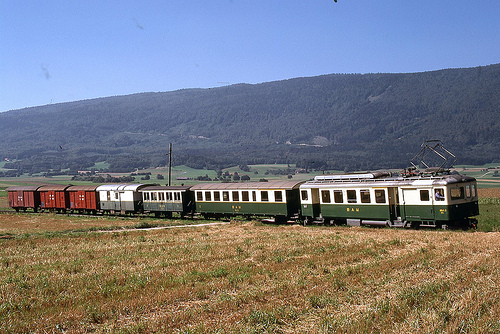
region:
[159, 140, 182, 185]
Tall brown telephone pole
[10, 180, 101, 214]
Three red train cars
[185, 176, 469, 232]
Two green and white train cars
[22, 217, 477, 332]
Brown grassy field in front of train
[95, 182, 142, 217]
One white and gray train car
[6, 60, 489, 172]
Hill covered with dark green trees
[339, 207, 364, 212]
Yellow train sign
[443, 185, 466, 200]
Open train window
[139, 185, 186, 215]
Green and white train car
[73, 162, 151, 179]
Brown patch of dirt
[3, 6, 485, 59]
this is the sky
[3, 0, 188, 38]
the sky is blue in color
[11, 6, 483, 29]
the sky is clear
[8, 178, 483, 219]
this is a train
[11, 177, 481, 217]
the train is long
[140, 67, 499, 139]
this is a hill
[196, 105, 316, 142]
the hill is covered with trees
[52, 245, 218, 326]
this is the grass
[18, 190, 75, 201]
the train is red in color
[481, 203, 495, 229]
the grass is green in color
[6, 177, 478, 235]
a train passing through a field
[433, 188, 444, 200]
the man driving the train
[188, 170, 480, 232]
two green and white train cars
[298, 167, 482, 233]
engine of the train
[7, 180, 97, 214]
three red colored train cars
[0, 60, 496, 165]
wooded mountain in the distance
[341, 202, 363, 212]
letters BLM written in yellow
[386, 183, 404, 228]
entrance to the trains engine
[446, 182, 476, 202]
front window of the train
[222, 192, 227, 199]
passenger in the train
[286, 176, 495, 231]
Green and cream train.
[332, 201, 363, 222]
Yellow letters on a train.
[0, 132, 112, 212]
Maroon and white caboose.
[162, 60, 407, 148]
Green trees on hill side.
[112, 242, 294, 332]
Tan and green grassy area.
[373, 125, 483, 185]
Metal traingular object.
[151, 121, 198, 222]
Telephone pole by train.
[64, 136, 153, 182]
Clear area with trees all around.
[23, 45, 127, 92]
Blue and white sky.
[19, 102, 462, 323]
Train beside a green hill side.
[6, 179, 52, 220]
A red car on a train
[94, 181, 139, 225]
A grey and white train car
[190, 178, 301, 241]
A green and white train car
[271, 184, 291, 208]
A window on a train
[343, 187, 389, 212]
Three windows on a train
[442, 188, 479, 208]
The windshield on a train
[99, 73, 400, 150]
A mountain in the background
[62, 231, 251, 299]
Dry grass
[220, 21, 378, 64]
A blue sky